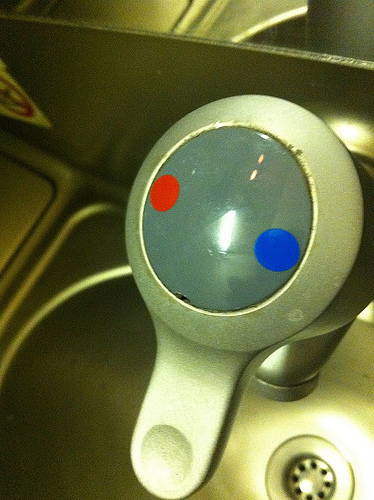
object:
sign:
[0, 57, 53, 133]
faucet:
[123, 90, 373, 500]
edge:
[176, 398, 184, 414]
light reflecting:
[206, 207, 244, 255]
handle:
[122, 93, 374, 374]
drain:
[265, 432, 355, 498]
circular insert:
[138, 124, 318, 318]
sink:
[0, 10, 372, 500]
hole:
[308, 460, 318, 469]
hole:
[318, 469, 326, 476]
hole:
[325, 482, 332, 490]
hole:
[317, 490, 326, 498]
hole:
[288, 471, 300, 483]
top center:
[142, 127, 310, 314]